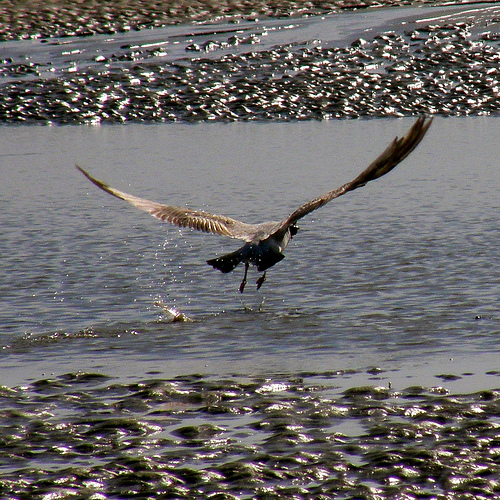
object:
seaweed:
[9, 369, 492, 498]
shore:
[0, 352, 499, 498]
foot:
[256, 276, 266, 290]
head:
[290, 225, 300, 235]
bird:
[75, 115, 435, 294]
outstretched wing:
[75, 162, 256, 243]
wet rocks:
[0, 0, 499, 125]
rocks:
[145, 61, 300, 126]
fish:
[153, 301, 189, 322]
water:
[4, 120, 499, 499]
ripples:
[227, 158, 297, 196]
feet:
[239, 279, 247, 294]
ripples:
[301, 223, 483, 328]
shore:
[3, 4, 499, 124]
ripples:
[0, 307, 336, 357]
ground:
[0, 0, 499, 498]